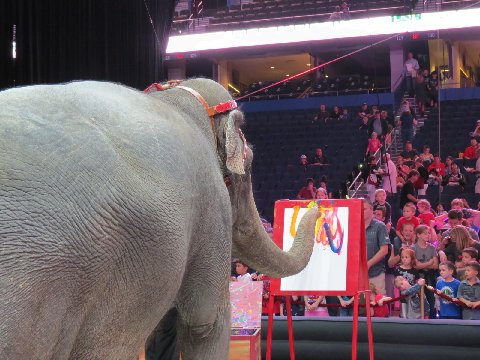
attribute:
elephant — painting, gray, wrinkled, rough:
[160, 76, 318, 300]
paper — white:
[284, 211, 348, 275]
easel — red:
[271, 195, 370, 296]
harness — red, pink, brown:
[206, 78, 283, 129]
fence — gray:
[261, 315, 473, 360]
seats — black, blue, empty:
[279, 160, 324, 183]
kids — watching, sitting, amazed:
[389, 195, 452, 277]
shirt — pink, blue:
[369, 137, 388, 158]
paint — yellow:
[287, 201, 325, 244]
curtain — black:
[17, 14, 163, 66]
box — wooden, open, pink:
[229, 315, 268, 359]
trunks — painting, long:
[248, 209, 330, 281]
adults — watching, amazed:
[357, 200, 407, 272]